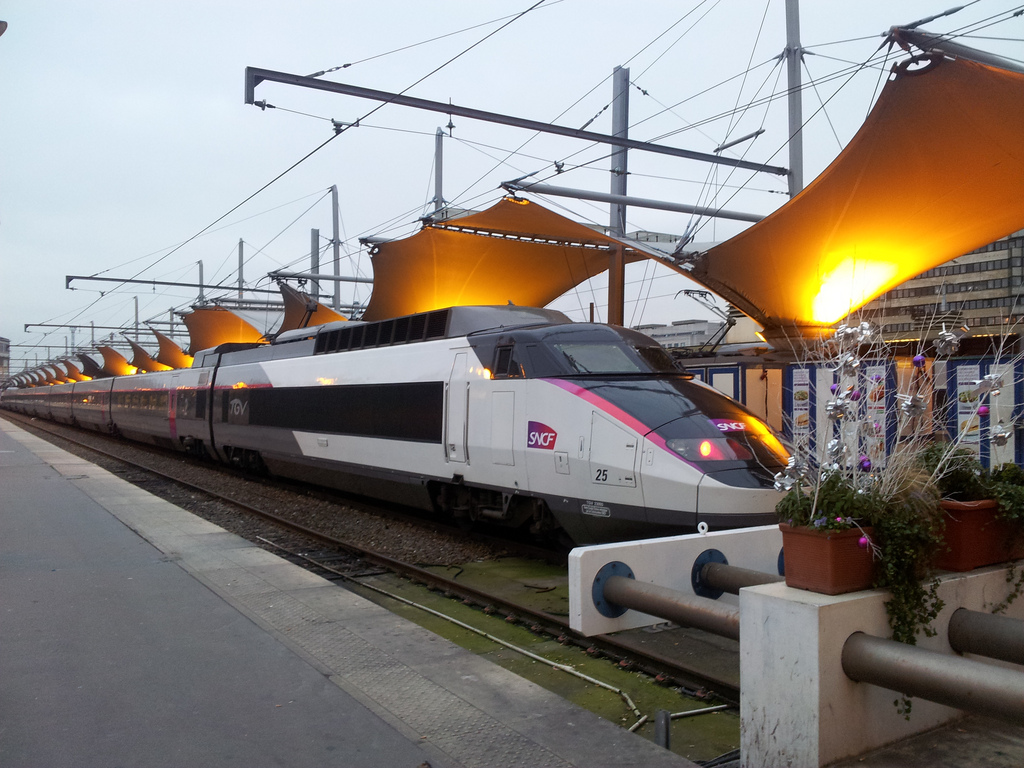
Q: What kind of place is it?
A: It is a street.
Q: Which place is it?
A: It is a street.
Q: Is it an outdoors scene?
A: Yes, it is outdoors.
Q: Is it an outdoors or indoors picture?
A: It is outdoors.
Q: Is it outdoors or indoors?
A: It is outdoors.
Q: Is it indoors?
A: No, it is outdoors.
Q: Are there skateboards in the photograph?
A: No, there are no skateboards.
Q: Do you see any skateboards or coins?
A: No, there are no skateboards or coins.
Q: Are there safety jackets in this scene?
A: No, there are no safety jackets.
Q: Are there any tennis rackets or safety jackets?
A: No, there are no safety jackets or tennis rackets.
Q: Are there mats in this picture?
A: No, there are no mats.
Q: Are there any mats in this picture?
A: No, there are no mats.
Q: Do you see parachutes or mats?
A: No, there are no mats or parachutes.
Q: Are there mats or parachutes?
A: No, there are no mats or parachutes.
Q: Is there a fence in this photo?
A: No, there are no fences.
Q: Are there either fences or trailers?
A: No, there are no fences or trailers.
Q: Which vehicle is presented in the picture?
A: The vehicle is a car.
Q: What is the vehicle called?
A: The vehicle is a car.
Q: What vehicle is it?
A: The vehicle is a car.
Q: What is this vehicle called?
A: This is a car.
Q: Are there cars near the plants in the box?
A: Yes, there is a car near the plants.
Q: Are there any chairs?
A: No, there are no chairs.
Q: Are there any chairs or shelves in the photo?
A: No, there are no chairs or shelves.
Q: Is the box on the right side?
A: Yes, the box is on the right of the image.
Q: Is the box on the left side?
A: No, the box is on the right of the image.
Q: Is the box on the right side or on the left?
A: The box is on the right of the image.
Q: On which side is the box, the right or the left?
A: The box is on the right of the image.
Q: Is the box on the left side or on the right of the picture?
A: The box is on the right of the image.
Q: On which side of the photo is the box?
A: The box is on the right of the image.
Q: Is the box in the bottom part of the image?
A: Yes, the box is in the bottom of the image.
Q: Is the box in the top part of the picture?
A: No, the box is in the bottom of the image.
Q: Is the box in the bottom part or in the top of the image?
A: The box is in the bottom of the image.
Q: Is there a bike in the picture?
A: No, there are no bikes.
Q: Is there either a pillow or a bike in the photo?
A: No, there are no bikes or pillows.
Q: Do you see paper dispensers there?
A: No, there are no paper dispensers.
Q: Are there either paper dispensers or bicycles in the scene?
A: No, there are no paper dispensers or bicycles.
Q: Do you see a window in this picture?
A: Yes, there are windows.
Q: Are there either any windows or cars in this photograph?
A: Yes, there are windows.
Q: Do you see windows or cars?
A: Yes, there are windows.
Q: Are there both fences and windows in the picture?
A: No, there are windows but no fences.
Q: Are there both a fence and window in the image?
A: No, there are windows but no fences.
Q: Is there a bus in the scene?
A: No, there are no buses.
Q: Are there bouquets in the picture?
A: No, there are no bouquets.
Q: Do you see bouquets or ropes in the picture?
A: No, there are no bouquets or ropes.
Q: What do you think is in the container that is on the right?
A: The plants are in the box.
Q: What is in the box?
A: The plants are in the box.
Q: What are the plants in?
A: The plants are in the box.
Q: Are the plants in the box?
A: Yes, the plants are in the box.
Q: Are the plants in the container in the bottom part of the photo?
A: Yes, the plants are in the box.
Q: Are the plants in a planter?
A: No, the plants are in the box.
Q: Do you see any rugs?
A: No, there are no rugs.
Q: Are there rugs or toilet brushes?
A: No, there are no rugs or toilet brushes.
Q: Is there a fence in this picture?
A: No, there are no fences.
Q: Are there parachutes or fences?
A: No, there are no fences or parachutes.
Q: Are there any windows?
A: Yes, there is a window.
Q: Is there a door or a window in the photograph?
A: Yes, there is a window.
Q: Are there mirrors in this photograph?
A: No, there are no mirrors.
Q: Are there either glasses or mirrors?
A: No, there are no mirrors or glasses.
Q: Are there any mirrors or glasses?
A: No, there are no mirrors or glasses.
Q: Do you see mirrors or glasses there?
A: No, there are no mirrors or glasses.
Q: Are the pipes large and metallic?
A: Yes, the pipes are large and metallic.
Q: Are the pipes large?
A: Yes, the pipes are large.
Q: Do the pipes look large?
A: Yes, the pipes are large.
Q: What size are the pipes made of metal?
A: The pipes are large.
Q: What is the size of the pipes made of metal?
A: The pipes are large.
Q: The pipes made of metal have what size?
A: The pipes are large.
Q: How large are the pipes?
A: The pipes are large.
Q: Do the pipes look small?
A: No, the pipes are large.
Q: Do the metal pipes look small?
A: No, the pipes are large.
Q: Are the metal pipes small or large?
A: The pipes are large.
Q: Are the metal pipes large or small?
A: The pipes are large.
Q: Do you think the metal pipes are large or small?
A: The pipes are large.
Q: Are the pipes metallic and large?
A: Yes, the pipes are metallic and large.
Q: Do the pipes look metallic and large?
A: Yes, the pipes are metallic and large.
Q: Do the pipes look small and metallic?
A: No, the pipes are metallic but large.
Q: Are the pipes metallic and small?
A: No, the pipes are metallic but large.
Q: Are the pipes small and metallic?
A: No, the pipes are metallic but large.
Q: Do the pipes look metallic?
A: Yes, the pipes are metallic.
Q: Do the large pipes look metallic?
A: Yes, the pipes are metallic.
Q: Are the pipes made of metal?
A: Yes, the pipes are made of metal.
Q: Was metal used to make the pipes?
A: Yes, the pipes are made of metal.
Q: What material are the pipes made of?
A: The pipes are made of metal.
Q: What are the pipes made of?
A: The pipes are made of metal.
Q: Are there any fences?
A: No, there are no fences.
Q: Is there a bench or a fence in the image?
A: No, there are no fences or benches.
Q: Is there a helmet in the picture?
A: No, there are no helmets.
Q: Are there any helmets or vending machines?
A: No, there are no helmets or vending machines.